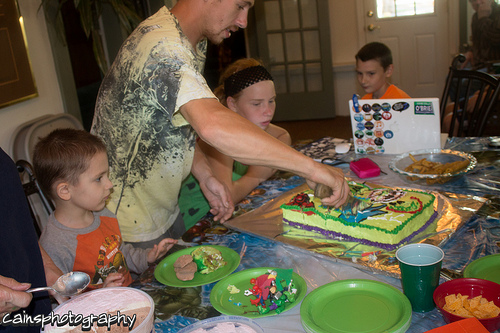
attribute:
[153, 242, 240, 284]
plate — green, plastic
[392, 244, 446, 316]
cup — green, plastic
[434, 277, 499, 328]
bowl — red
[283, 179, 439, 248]
cake — green, cut, yellow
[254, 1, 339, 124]
door — glass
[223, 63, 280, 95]
headband — black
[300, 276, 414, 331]
plates — green, stacked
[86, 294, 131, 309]
ice cream — neopolitan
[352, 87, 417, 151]
shirt — orange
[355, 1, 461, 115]
door — white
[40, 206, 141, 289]
shirt — gray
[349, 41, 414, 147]
boy — watching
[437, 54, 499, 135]
chair — black